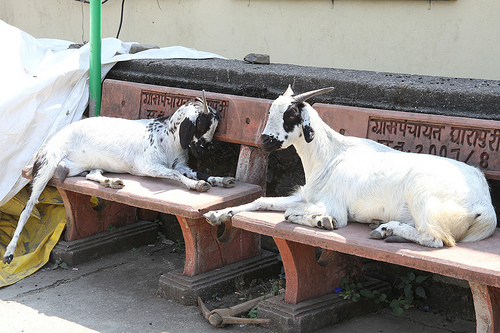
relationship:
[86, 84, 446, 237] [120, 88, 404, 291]
goats on benches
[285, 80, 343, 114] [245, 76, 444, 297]
antler on goat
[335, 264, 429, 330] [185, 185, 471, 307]
weeds under bench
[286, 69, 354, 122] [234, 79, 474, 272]
horn on goats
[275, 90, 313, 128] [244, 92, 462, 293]
eye on goat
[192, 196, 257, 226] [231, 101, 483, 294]
hoof on goat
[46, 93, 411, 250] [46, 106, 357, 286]
goats on benches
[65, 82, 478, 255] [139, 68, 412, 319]
goats on bench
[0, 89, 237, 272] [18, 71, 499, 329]
goat on bench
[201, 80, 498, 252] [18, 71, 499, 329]
goat on bench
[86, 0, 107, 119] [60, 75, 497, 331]
pole next to bench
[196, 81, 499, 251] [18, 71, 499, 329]
animal on bench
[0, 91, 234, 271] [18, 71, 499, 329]
animal on bench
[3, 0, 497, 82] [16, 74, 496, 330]
wall behind benches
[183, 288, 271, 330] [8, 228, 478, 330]
ax on floor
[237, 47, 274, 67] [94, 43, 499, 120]
rock on wall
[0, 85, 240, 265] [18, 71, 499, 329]
cabro on bench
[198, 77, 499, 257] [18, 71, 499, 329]
cabro on bench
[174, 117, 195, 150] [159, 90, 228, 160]
spots on head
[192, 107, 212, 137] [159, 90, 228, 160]
spots on head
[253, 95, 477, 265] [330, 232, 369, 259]
goat on bench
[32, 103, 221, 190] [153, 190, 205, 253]
goat sleeping on bench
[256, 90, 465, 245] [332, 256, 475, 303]
goat relaxing on bench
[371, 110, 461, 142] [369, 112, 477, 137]
bench with lettering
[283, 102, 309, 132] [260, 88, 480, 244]
eye of a goat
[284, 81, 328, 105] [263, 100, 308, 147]
horns atop head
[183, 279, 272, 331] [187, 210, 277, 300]
axe between benches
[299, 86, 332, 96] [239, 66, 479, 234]
horn of a goat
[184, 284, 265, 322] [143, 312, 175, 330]
pickaxe on the ground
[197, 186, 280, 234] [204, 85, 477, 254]
leg of the goat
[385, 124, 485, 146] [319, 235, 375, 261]
writing on the bench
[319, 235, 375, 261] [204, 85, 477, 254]
bench behind goat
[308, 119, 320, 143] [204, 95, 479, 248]
ear of the goat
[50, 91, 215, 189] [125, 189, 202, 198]
goat on the bench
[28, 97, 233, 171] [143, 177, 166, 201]
goat is sleeping on bench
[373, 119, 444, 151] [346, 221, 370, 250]
writing on the bench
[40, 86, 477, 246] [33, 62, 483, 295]
goats on the bench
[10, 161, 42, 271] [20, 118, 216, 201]
leg of goat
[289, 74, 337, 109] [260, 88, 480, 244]
horn of goat